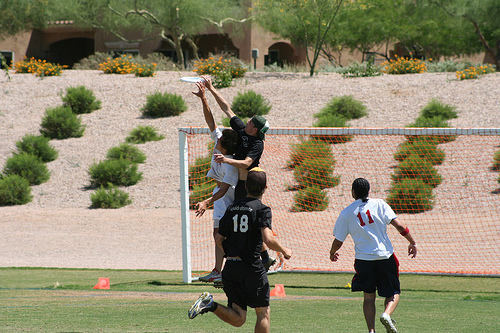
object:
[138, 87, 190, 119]
bush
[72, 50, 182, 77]
bush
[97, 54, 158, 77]
flowers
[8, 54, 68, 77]
flowers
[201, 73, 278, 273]
man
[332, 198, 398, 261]
shirt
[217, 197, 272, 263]
shirt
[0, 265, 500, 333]
ground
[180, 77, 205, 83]
frisbee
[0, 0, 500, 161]
air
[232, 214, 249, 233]
number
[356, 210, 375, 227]
number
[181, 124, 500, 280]
net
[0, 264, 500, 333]
field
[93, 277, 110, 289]
cone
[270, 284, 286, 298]
cone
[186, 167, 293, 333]
man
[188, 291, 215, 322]
shoe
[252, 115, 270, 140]
hat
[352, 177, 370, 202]
hair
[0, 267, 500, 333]
grass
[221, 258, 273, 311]
shorts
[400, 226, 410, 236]
band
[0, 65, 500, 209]
hill